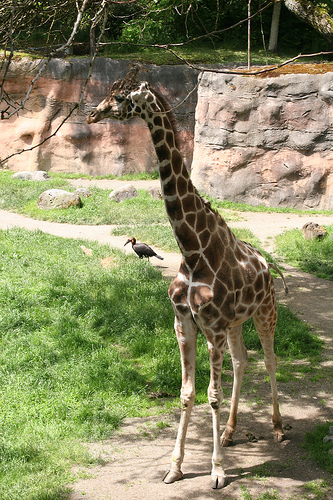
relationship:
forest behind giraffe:
[1, 0, 333, 51] [86, 63, 289, 488]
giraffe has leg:
[86, 63, 289, 488] [206, 339, 226, 491]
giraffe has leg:
[86, 63, 289, 488] [162, 320, 196, 484]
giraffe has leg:
[86, 63, 289, 488] [221, 328, 246, 446]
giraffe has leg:
[86, 63, 289, 488] [253, 314, 285, 445]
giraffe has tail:
[86, 63, 289, 488] [267, 264, 289, 295]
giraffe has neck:
[86, 63, 289, 488] [144, 112, 231, 274]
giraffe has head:
[86, 63, 289, 488] [86, 62, 151, 124]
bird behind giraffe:
[124, 236, 165, 265] [86, 63, 289, 488]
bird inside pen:
[124, 236, 165, 265] [1, 59, 332, 500]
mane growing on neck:
[147, 85, 180, 149] [144, 112, 231, 274]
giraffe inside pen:
[86, 63, 289, 488] [1, 59, 332, 500]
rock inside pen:
[37, 189, 84, 209] [1, 59, 332, 500]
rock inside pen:
[108, 183, 137, 201] [1, 59, 332, 500]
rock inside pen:
[12, 171, 48, 181] [1, 59, 332, 500]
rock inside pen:
[302, 222, 329, 243] [1, 59, 332, 500]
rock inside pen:
[146, 187, 160, 201] [1, 59, 332, 500]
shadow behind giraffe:
[6, 257, 332, 499] [86, 63, 289, 488]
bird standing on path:
[124, 236, 165, 265] [1, 209, 183, 277]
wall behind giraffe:
[0, 59, 333, 210] [86, 63, 289, 488]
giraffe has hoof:
[86, 63, 289, 488] [211, 476, 225, 488]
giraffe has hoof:
[86, 63, 289, 488] [162, 470, 178, 484]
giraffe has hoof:
[86, 63, 289, 488] [273, 431, 283, 442]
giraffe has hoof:
[86, 63, 289, 488] [217, 436, 231, 448]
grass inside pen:
[1, 170, 169, 224] [1, 59, 332, 500]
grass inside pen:
[273, 224, 333, 278] [1, 59, 332, 500]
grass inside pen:
[1, 226, 181, 499] [1, 59, 332, 500]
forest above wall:
[1, 0, 333, 51] [0, 59, 333, 210]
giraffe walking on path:
[86, 63, 289, 488] [0, 209, 332, 499]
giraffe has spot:
[86, 63, 289, 488] [163, 198, 184, 221]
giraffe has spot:
[86, 63, 289, 488] [154, 144, 170, 164]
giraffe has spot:
[86, 63, 289, 488] [199, 231, 210, 247]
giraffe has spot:
[86, 63, 289, 488] [219, 228, 230, 247]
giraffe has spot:
[86, 63, 289, 488] [242, 287, 254, 306]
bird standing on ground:
[124, 236, 165, 265] [2, 174, 333, 499]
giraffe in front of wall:
[86, 63, 289, 488] [0, 59, 333, 210]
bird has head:
[124, 236, 165, 265] [124, 236, 136, 246]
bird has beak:
[124, 236, 165, 265] [124, 240, 129, 247]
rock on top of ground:
[12, 171, 48, 181] [2, 174, 333, 499]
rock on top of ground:
[37, 189, 84, 209] [2, 174, 333, 499]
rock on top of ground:
[108, 183, 137, 201] [2, 174, 333, 499]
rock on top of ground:
[146, 187, 160, 201] [2, 174, 333, 499]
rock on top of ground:
[302, 222, 329, 243] [2, 174, 333, 499]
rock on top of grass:
[12, 171, 48, 181] [1, 170, 169, 224]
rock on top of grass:
[37, 189, 84, 209] [1, 170, 169, 224]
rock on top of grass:
[108, 183, 137, 201] [1, 170, 169, 224]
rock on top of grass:
[146, 187, 160, 201] [1, 170, 169, 224]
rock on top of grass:
[74, 189, 92, 199] [1, 170, 169, 224]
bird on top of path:
[124, 236, 165, 265] [1, 209, 183, 277]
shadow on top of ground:
[6, 257, 332, 499] [2, 174, 333, 499]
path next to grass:
[1, 209, 183, 277] [1, 170, 169, 224]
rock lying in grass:
[12, 171, 48, 181] [1, 170, 169, 224]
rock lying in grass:
[37, 189, 84, 209] [1, 170, 169, 224]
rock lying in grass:
[74, 189, 92, 199] [1, 170, 169, 224]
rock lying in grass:
[108, 183, 137, 201] [1, 170, 169, 224]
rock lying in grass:
[146, 187, 160, 201] [1, 170, 169, 224]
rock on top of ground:
[74, 189, 92, 199] [2, 174, 333, 499]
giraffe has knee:
[86, 63, 289, 488] [180, 389, 196, 412]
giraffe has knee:
[86, 63, 289, 488] [207, 385, 223, 410]